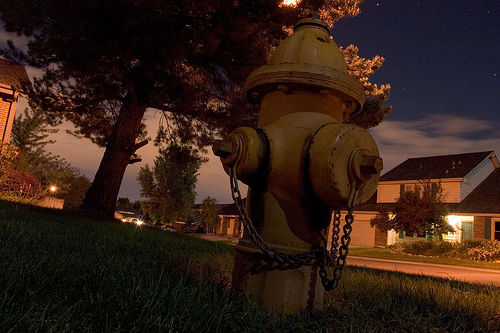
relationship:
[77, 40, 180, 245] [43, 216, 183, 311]
tree in grass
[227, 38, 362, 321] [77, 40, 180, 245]
hydrant near tree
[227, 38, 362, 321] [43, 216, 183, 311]
hydrant in grass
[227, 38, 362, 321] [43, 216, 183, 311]
hydrant on grass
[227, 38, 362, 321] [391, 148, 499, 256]
hydrant near house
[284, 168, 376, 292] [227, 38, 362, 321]
chain on hydrant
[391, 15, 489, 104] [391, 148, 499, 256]
sky above house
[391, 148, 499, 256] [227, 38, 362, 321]
house near hydrant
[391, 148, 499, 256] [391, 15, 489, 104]
house below sky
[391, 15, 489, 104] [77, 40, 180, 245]
sky near tree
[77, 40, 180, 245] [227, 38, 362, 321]
tree near hydrant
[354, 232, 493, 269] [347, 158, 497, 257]
garden in front of house